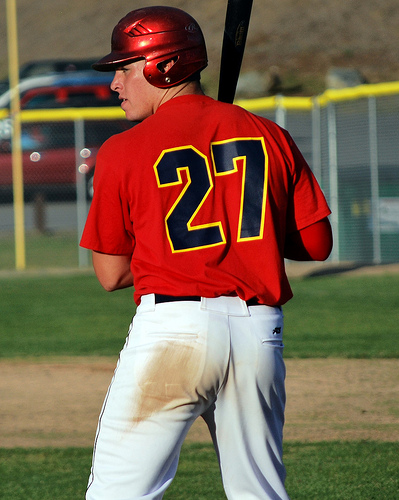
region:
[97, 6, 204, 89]
red helmet on head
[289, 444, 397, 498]
green grass on field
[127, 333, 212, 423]
dirt stain on pants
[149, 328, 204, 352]
pocket on the pants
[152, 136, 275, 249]
number 27 on back of jersey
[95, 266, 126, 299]
left elbow on man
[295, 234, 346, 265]
right elbow on man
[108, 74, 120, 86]
nose on the man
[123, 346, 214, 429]
The man has dirt on his pants.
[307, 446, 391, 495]
The grass is green.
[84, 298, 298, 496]
The man has on white pants.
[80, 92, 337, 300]
The man is wearing a red shirt.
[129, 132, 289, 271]
The shirt has the number 27 on it.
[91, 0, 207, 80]
The man has on a helmet.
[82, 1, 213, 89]
The helmet is red in color.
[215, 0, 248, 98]
The bat is black in color.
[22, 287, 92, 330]
The grass is green.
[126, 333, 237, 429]
a dirty spot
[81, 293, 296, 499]
a pair of pants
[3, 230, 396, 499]
a baseball field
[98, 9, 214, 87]
the red helmet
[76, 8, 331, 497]
a man on the field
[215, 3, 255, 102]
a hard bat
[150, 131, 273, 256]
the number 27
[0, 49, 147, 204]
the cars in the lot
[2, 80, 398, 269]
a fence around the field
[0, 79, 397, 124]
the yellow trimming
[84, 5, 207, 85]
red helmet on player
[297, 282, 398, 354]
grass on the baseball field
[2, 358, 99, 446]
dirt on the ground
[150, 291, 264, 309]
black belt on player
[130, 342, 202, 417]
dirt stain on player's pants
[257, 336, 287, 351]
right pocket on pants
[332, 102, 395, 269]
fence around the field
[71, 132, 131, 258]
left sleeve on shirt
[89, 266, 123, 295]
the man's left elbow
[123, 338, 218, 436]
dirt stains on the butt of the pants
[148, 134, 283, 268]
numbers on the back of the jersey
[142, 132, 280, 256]
yellow outline around the numbers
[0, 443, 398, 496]
green grass on the field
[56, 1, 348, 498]
player holding a bat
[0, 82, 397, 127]
yellow line at the top of the fence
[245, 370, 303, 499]
wrinkles in the pant leg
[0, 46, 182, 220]
a row of parked cars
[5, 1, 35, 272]
yellow pole on the edge of the field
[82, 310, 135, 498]
black stripe on the side of the pant leg